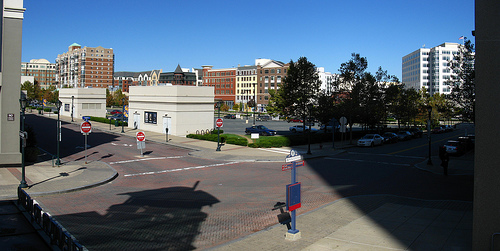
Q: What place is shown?
A: It is a road.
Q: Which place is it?
A: It is a road.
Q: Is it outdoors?
A: Yes, it is outdoors.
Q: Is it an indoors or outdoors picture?
A: It is outdoors.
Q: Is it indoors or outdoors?
A: It is outdoors.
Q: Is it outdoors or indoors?
A: It is outdoors.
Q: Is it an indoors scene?
A: No, it is outdoors.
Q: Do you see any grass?
A: Yes, there is grass.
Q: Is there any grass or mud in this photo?
A: Yes, there is grass.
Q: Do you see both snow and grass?
A: No, there is grass but no snow.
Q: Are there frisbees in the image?
A: No, there are no frisbees.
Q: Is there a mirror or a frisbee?
A: No, there are no frisbees or mirrors.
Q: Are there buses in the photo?
A: No, there are no buses.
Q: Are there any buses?
A: No, there are no buses.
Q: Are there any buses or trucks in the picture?
A: No, there are no buses or trucks.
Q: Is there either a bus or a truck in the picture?
A: No, there are no buses or trucks.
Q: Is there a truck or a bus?
A: No, there are no buses or trucks.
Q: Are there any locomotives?
A: No, there are no locomotives.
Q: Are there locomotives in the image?
A: No, there are no locomotives.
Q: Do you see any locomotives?
A: No, there are no locomotives.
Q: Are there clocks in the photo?
A: No, there are no clocks.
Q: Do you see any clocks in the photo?
A: No, there are no clocks.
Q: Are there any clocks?
A: No, there are no clocks.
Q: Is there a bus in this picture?
A: No, there are no buses.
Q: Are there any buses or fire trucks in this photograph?
A: No, there are no buses or fire trucks.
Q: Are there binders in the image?
A: No, there are no binders.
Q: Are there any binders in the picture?
A: No, there are no binders.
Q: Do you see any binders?
A: No, there are no binders.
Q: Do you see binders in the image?
A: No, there are no binders.